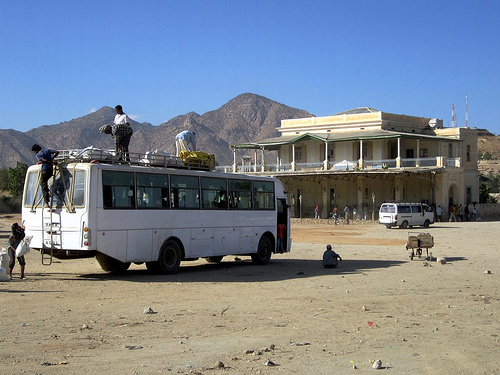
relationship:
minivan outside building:
[378, 202, 435, 229] [216, 111, 481, 222]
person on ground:
[322, 244, 341, 267] [0, 215, 498, 374]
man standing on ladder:
[31, 144, 59, 207] [40, 156, 60, 265]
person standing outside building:
[315, 204, 322, 223] [216, 111, 481, 222]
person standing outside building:
[332, 206, 340, 222] [216, 111, 481, 222]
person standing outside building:
[343, 205, 352, 224] [216, 111, 481, 222]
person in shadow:
[322, 244, 341, 267] [78, 258, 409, 283]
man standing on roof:
[112, 105, 133, 164] [26, 160, 280, 182]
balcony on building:
[212, 157, 463, 175] [216, 111, 481, 222]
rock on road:
[484, 268, 492, 276] [2, 220, 498, 373]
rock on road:
[373, 358, 384, 370] [2, 220, 498, 373]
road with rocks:
[2, 220, 498, 373] [255, 343, 277, 358]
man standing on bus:
[31, 144, 59, 207] [24, 162, 290, 272]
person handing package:
[7, 222, 29, 281] [16, 233, 32, 257]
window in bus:
[105, 186, 136, 209] [24, 162, 290, 272]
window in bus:
[172, 186, 202, 208] [24, 162, 290, 272]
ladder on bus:
[40, 156, 60, 265] [24, 162, 290, 272]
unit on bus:
[190, 229, 216, 255] [24, 162, 290, 272]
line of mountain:
[0, 93, 315, 171] [196, 94, 317, 148]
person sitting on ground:
[322, 244, 341, 267] [0, 215, 498, 374]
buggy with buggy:
[406, 233, 434, 261] [405, 232, 434, 261]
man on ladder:
[31, 144, 59, 207] [40, 156, 60, 265]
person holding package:
[7, 222, 29, 281] [16, 233, 32, 257]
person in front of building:
[343, 205, 352, 224] [216, 111, 481, 222]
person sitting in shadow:
[322, 244, 341, 267] [78, 258, 409, 283]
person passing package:
[7, 222, 29, 281] [16, 233, 32, 257]